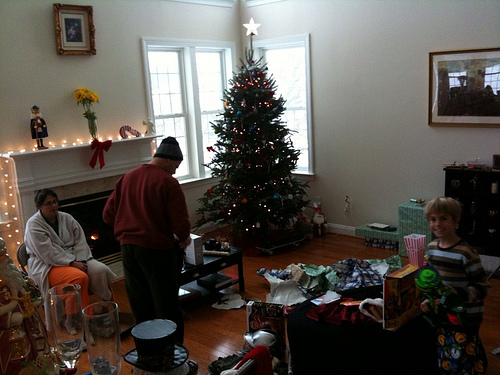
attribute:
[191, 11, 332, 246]
christmas tree — decorated, green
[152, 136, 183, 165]
hat — black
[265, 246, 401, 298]
wrapping paper — ripped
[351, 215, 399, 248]
present — un-opened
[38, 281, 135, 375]
empty glasses — flutes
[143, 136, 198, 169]
ski cap — black, grey